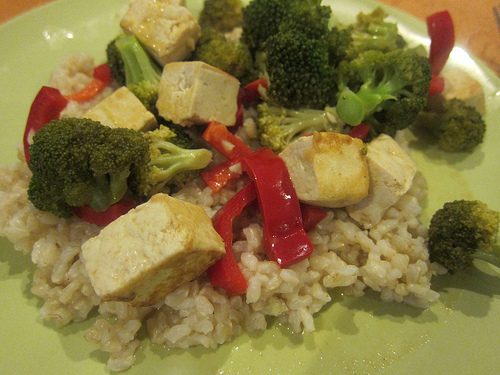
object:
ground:
[447, 159, 488, 185]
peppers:
[201, 120, 328, 297]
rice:
[0, 53, 448, 373]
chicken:
[78, 0, 417, 310]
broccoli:
[27, 0, 500, 279]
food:
[0, 0, 500, 373]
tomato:
[22, 63, 133, 226]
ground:
[317, 132, 358, 173]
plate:
[0, 0, 500, 375]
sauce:
[134, 0, 175, 54]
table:
[1, 0, 500, 375]